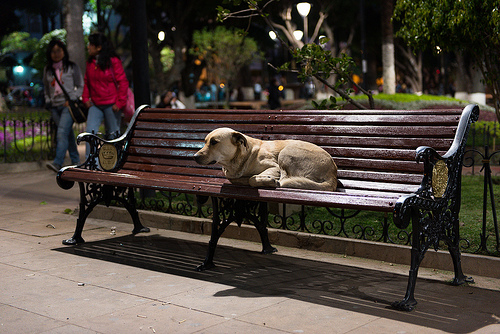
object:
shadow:
[56, 217, 500, 332]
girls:
[44, 36, 82, 174]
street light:
[294, 1, 314, 19]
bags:
[65, 93, 93, 124]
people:
[85, 36, 135, 169]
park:
[9, 0, 499, 287]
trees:
[388, 0, 499, 111]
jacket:
[85, 57, 130, 110]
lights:
[292, 0, 317, 20]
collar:
[237, 148, 252, 172]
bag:
[120, 88, 142, 116]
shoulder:
[107, 55, 126, 66]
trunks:
[378, 47, 397, 96]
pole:
[133, 22, 153, 109]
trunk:
[402, 54, 426, 95]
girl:
[82, 30, 140, 167]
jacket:
[41, 61, 86, 105]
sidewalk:
[18, 247, 499, 330]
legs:
[395, 203, 440, 313]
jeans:
[85, 107, 124, 173]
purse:
[120, 90, 138, 112]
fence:
[95, 122, 500, 249]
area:
[455, 158, 498, 222]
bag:
[64, 93, 88, 123]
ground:
[0, 205, 495, 327]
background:
[24, 13, 496, 98]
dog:
[193, 125, 342, 192]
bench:
[59, 103, 480, 310]